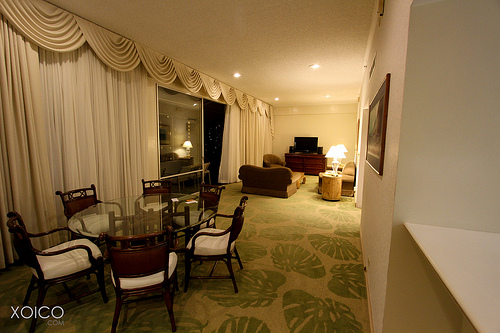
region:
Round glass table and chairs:
[6, 168, 266, 310]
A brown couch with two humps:
[235, 160, 301, 200]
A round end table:
[316, 164, 361, 206]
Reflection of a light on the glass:
[168, 133, 195, 163]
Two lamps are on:
[324, 137, 351, 179]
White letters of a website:
[11, 303, 69, 330]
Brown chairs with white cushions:
[14, 181, 289, 321]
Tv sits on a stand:
[280, 126, 327, 165]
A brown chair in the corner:
[261, 148, 290, 170]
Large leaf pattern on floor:
[213, 186, 373, 332]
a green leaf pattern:
[277, 242, 317, 279]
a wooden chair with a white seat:
[188, 205, 265, 274]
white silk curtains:
[69, 78, 121, 165]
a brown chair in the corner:
[262, 151, 286, 166]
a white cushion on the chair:
[40, 257, 85, 275]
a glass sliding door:
[161, 94, 201, 157]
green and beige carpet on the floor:
[261, 215, 334, 304]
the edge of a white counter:
[412, 240, 489, 301]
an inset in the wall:
[411, 286, 454, 322]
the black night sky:
[210, 108, 222, 154]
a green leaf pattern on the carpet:
[272, 240, 334, 285]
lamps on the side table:
[328, 136, 350, 170]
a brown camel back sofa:
[241, 159, 306, 199]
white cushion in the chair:
[49, 260, 77, 275]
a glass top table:
[94, 185, 185, 229]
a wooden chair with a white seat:
[102, 238, 199, 330]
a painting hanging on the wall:
[371, 85, 386, 175]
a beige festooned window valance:
[49, 14, 143, 63]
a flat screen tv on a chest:
[292, 134, 319, 151]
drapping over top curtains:
[69, 19, 151, 73]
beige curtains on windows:
[44, 103, 116, 133]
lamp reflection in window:
[165, 98, 202, 175]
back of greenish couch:
[236, 164, 293, 190]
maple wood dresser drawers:
[285, 154, 325, 171]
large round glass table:
[94, 208, 179, 226]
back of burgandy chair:
[100, 234, 177, 274]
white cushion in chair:
[49, 243, 78, 249]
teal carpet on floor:
[255, 256, 272, 267]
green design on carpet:
[275, 240, 309, 275]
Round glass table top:
[70, 196, 215, 243]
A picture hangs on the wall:
[363, 86, 405, 174]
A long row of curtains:
[16, 8, 283, 205]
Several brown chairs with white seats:
[9, 176, 263, 329]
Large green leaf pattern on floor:
[248, 194, 363, 331]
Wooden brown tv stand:
[282, 147, 331, 190]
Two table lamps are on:
[326, 141, 353, 176]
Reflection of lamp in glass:
[181, 137, 198, 157]